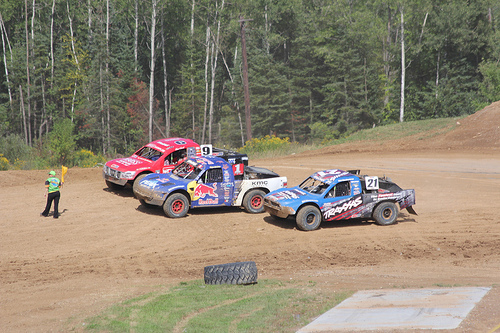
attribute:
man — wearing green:
[41, 170, 61, 219]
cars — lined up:
[120, 125, 431, 232]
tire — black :
[159, 246, 326, 290]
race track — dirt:
[3, 142, 499, 329]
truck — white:
[257, 160, 417, 232]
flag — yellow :
[50, 154, 87, 190]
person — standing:
[27, 163, 66, 222]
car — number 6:
[101, 137, 174, 188]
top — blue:
[182, 153, 231, 171]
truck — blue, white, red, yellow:
[126, 148, 290, 220]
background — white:
[15, 24, 489, 324]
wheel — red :
[242, 190, 268, 214]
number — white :
[363, 175, 379, 190]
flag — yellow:
[58, 157, 70, 180]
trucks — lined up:
[97, 118, 427, 232]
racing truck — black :
[262, 168, 415, 230]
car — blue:
[261, 166, 418, 230]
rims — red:
[160, 196, 195, 224]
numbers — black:
[187, 140, 219, 159]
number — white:
[225, 160, 248, 178]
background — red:
[230, 160, 240, 171]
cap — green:
[23, 164, 53, 178]